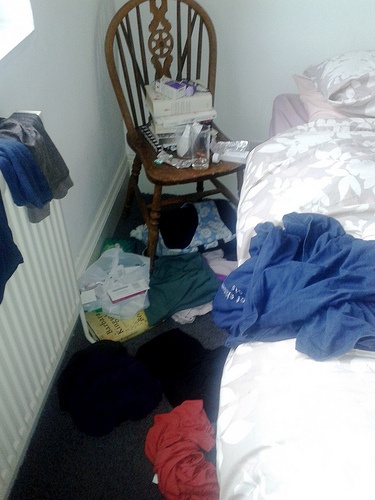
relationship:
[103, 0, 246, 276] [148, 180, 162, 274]
brown chair has leg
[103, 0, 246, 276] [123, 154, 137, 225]
brown chair has leg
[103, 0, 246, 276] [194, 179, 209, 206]
brown chair has leg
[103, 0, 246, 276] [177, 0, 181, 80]
brown chair has spindle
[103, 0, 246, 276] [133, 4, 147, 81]
brown chair has spindle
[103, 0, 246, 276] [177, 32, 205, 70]
brown chair has spindle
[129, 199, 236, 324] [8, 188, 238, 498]
clothing on floor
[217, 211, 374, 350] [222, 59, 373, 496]
clothes on bed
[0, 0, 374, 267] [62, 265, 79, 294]
wall has part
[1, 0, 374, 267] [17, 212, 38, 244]
wall has part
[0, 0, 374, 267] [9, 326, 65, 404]
wall has part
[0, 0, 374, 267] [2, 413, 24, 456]
wall has part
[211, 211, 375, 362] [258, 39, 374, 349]
clothes on bed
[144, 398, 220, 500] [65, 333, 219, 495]
clothes on floor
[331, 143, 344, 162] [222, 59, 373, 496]
leaf on bed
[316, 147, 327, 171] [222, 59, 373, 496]
leaf on bed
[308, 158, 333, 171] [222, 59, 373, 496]
leaf on bed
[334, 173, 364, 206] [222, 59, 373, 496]
leaf on bed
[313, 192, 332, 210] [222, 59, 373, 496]
leaf on bed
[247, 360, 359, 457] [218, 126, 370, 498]
light shining bed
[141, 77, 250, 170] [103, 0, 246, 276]
stacked stuff stacked brown chair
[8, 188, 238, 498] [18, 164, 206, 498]
floor carpeted dark color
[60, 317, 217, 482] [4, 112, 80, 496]
clothes on heater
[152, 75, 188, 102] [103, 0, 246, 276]
box sitting brown chair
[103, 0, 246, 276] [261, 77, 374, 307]
brown chair sitting bed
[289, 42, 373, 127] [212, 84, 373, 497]
pillow on bed